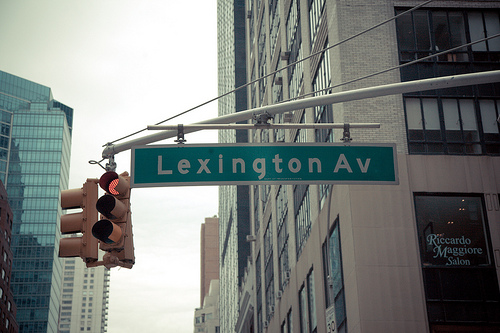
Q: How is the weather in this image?
A: It is cloudy.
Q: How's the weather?
A: It is cloudy.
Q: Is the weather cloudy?
A: Yes, it is cloudy.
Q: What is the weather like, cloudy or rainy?
A: It is cloudy.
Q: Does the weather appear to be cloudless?
A: No, it is cloudy.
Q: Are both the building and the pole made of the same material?
A: No, the building is made of glass and the pole is made of metal.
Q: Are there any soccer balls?
A: No, there are no soccer balls.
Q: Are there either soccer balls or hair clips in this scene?
A: No, there are no soccer balls or hair clips.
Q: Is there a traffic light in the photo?
A: Yes, there is a traffic light.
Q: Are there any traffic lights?
A: Yes, there is a traffic light.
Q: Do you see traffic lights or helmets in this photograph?
A: Yes, there is a traffic light.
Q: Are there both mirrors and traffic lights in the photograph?
A: No, there is a traffic light but no mirrors.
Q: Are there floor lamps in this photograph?
A: No, there are no floor lamps.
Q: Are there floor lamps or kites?
A: No, there are no floor lamps or kites.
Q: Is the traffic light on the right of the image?
A: No, the traffic light is on the left of the image.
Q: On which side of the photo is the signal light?
A: The signal light is on the left of the image.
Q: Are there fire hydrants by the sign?
A: No, there is a traffic light by the sign.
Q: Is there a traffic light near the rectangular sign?
A: Yes, there is a traffic light near the sign.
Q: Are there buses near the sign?
A: No, there is a traffic light near the sign.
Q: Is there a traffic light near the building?
A: Yes, there is a traffic light near the building.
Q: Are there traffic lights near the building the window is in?
A: Yes, there is a traffic light near the building.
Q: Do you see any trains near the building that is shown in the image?
A: No, there is a traffic light near the building.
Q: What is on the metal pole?
A: The traffic light is on the pole.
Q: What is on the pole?
A: The traffic light is on the pole.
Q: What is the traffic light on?
A: The traffic light is on the pole.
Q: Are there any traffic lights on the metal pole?
A: Yes, there is a traffic light on the pole.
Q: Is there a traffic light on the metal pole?
A: Yes, there is a traffic light on the pole.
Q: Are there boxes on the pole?
A: No, there is a traffic light on the pole.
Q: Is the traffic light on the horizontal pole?
A: Yes, the traffic light is on the pole.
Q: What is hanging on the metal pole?
A: The traffic light is hanging on the pole.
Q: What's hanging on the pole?
A: The traffic light is hanging on the pole.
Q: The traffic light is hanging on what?
A: The traffic light is hanging on the pole.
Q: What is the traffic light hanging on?
A: The traffic light is hanging on the pole.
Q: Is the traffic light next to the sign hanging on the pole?
A: Yes, the traffic light is hanging on the pole.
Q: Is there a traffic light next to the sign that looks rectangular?
A: Yes, there is a traffic light next to the sign.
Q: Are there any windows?
A: Yes, there is a window.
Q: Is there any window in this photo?
A: Yes, there is a window.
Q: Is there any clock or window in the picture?
A: Yes, there is a window.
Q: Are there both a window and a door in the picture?
A: No, there is a window but no doors.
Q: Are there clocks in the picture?
A: No, there are no clocks.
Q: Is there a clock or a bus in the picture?
A: No, there are no clocks or buses.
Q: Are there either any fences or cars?
A: No, there are no fences or cars.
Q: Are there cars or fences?
A: No, there are no fences or cars.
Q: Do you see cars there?
A: No, there are no cars.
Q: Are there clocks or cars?
A: No, there are no cars or clocks.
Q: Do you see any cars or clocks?
A: No, there are no cars or clocks.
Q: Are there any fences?
A: No, there are no fences.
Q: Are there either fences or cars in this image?
A: No, there are no fences or cars.